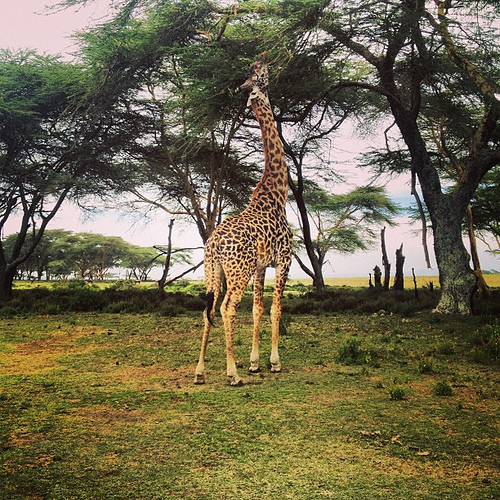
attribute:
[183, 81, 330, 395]
giraffe — standing, eating, yellow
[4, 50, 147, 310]
tree — green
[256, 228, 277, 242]
spot — yellow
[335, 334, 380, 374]
patches — weeds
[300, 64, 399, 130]
limbs — broken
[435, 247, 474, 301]
moss — growing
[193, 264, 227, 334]
tail — black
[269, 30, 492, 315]
trees — grouped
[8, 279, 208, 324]
bushes — small, tall, lined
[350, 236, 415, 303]
trunks — dry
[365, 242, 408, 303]
stump — dead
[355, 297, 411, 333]
fungus — growing